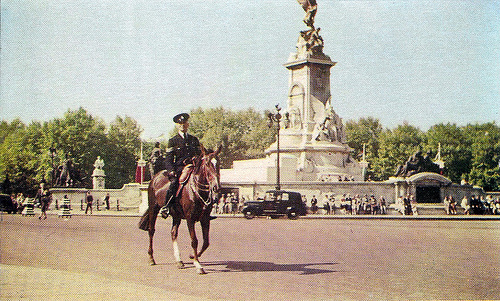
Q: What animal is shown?
A: A horse.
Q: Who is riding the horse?
A: A man.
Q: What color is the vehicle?
A: Black.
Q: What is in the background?
A: A statue.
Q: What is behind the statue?
A: Trees.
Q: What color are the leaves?
A: Green.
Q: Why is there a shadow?
A: It is sunny.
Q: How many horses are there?
A: One.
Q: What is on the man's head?
A: A hat.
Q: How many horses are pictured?
A: One.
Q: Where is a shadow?
A: On the ground.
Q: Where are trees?
A: In the distance.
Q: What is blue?
A: Sky.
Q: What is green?
A: Trees.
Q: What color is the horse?
A: Brown and white.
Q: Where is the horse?
A: On the street.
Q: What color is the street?
A: Brown.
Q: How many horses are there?
A: One.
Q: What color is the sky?
A: Blue.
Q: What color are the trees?
A: Green.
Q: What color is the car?
A: Black.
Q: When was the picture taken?
A: Daytime.